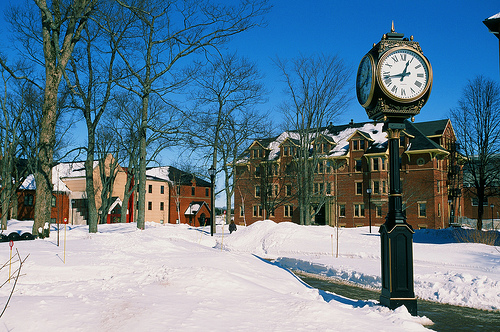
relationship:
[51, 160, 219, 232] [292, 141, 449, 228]
building with walls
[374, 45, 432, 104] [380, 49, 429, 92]
clock with numerals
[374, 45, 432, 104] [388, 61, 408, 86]
clock with face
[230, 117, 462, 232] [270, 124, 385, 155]
building with snow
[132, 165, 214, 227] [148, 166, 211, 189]
building with roof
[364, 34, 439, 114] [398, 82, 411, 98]
clock with numerals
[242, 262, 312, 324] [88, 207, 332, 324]
snow on ground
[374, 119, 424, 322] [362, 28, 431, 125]
pole under clock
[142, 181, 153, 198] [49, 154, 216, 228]
window on building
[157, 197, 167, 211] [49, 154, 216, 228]
window on building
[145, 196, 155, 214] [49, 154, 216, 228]
window on building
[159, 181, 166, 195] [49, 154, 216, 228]
window on building